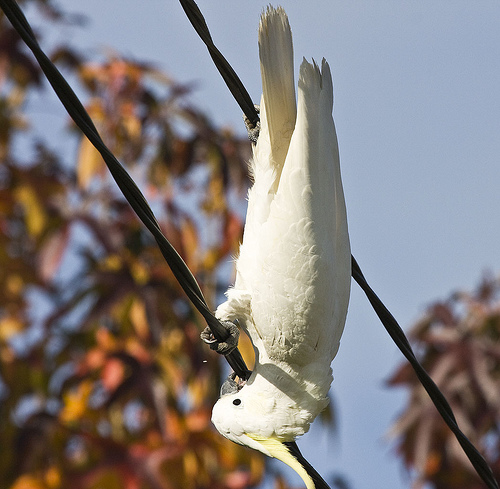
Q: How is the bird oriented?
A: Upside down.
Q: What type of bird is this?
A: Cockatoo.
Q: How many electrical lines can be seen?
A: Two.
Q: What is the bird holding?
A: Electrical line.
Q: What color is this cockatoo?
A: White.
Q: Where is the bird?
A: On a wire.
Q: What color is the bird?
A: White.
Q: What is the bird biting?
A: A wire.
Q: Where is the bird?
A: On a wire.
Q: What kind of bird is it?
A: Parrot.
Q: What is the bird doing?
A: Hanging upside down.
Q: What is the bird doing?
A: Biting the wire.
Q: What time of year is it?
A: Fall.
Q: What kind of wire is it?
A: Electrical.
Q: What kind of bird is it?
A: Cockatiel.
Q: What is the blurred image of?
A: Tree.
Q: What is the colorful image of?
A: Tree.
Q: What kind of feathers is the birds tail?
A: White.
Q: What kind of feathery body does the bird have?
A: White feather.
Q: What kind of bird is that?
A: Parrot.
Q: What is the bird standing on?
A: Black wire.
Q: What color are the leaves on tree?
A: Orange and yellow.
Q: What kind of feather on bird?
A: Tail feathers.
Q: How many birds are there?
A: 1.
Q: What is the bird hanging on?
A: Wires.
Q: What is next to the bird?
A: Tree.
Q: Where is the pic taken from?
A: Outdoors.